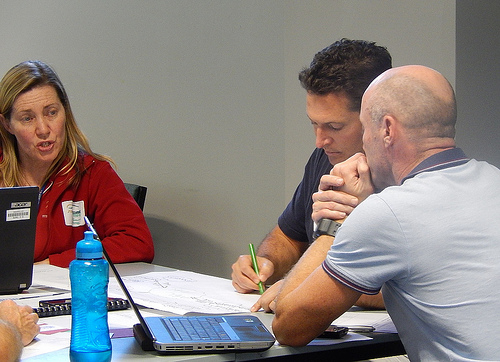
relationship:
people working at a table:
[3, 27, 498, 361] [6, 240, 395, 362]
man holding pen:
[252, 38, 409, 313] [247, 235, 264, 296]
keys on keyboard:
[163, 314, 224, 342] [149, 306, 269, 349]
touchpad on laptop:
[235, 321, 253, 335] [81, 211, 275, 355]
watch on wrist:
[309, 217, 342, 237] [310, 205, 361, 253]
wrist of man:
[310, 205, 361, 253] [246, 65, 496, 361]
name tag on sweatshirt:
[61, 199, 85, 230] [5, 155, 154, 274]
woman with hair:
[0, 53, 154, 264] [0, 65, 95, 192]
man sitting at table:
[252, 38, 409, 313] [6, 240, 395, 362]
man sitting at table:
[246, 65, 496, 361] [6, 240, 395, 362]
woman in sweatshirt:
[0, 53, 154, 264] [5, 155, 154, 274]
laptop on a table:
[81, 211, 275, 355] [6, 240, 395, 362]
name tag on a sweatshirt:
[61, 199, 85, 230] [5, 155, 154, 274]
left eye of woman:
[45, 110, 66, 122] [0, 53, 154, 264]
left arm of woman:
[56, 212, 155, 279] [0, 53, 154, 264]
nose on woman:
[35, 117, 57, 138] [0, 53, 154, 264]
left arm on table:
[56, 212, 155, 279] [6, 240, 395, 362]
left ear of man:
[383, 117, 402, 150] [246, 65, 496, 361]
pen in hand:
[247, 235, 264, 296] [229, 250, 276, 296]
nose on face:
[312, 126, 334, 151] [302, 89, 367, 166]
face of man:
[302, 89, 367, 166] [252, 38, 409, 313]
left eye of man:
[328, 120, 345, 137] [252, 38, 409, 313]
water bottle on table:
[67, 227, 115, 359] [6, 240, 395, 362]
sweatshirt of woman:
[5, 155, 154, 274] [0, 53, 154, 264]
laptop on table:
[81, 211, 275, 355] [6, 240, 395, 362]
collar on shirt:
[395, 146, 471, 181] [315, 141, 499, 360]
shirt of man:
[315, 141, 499, 360] [246, 65, 496, 361]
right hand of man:
[309, 170, 356, 224] [246, 65, 496, 361]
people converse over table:
[3, 27, 498, 361] [6, 240, 395, 362]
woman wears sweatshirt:
[0, 53, 154, 264] [5, 155, 154, 274]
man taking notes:
[252, 38, 409, 313] [211, 237, 286, 316]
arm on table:
[3, 289, 58, 362] [6, 240, 395, 362]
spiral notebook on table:
[18, 286, 131, 317] [6, 240, 395, 362]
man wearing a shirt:
[246, 65, 496, 361] [315, 141, 499, 360]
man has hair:
[252, 38, 409, 313] [289, 25, 393, 107]